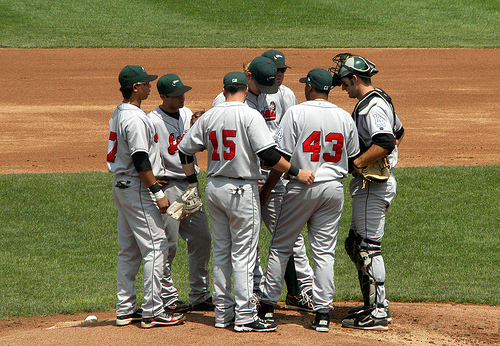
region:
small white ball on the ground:
[80, 306, 114, 328]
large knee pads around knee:
[351, 228, 406, 283]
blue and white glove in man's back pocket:
[92, 173, 147, 204]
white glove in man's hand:
[152, 184, 217, 237]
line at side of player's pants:
[356, 180, 379, 302]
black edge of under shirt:
[246, 140, 290, 175]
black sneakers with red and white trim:
[129, 306, 195, 329]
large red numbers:
[300, 123, 363, 177]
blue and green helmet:
[327, 50, 379, 79]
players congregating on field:
[98, 34, 429, 276]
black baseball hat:
[118, 66, 157, 83]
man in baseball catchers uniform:
[333, 54, 408, 328]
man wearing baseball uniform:
[185, 69, 278, 334]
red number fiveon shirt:
[222, 126, 236, 162]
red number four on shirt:
[305, 129, 322, 164]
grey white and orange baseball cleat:
[141, 311, 187, 326]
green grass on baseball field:
[2, 1, 497, 53]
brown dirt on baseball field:
[1, 47, 498, 169]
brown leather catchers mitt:
[364, 148, 391, 186]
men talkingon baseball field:
[110, 55, 397, 328]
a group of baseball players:
[51, 26, 432, 336]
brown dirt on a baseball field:
[43, 315, 495, 344]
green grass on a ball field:
[405, 170, 492, 276]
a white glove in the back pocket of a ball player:
[225, 181, 247, 198]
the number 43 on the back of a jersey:
[303, 130, 343, 167]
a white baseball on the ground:
[84, 312, 99, 324]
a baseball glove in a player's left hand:
[355, 164, 392, 188]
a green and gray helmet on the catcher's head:
[335, 56, 376, 78]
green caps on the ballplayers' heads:
[107, 40, 335, 105]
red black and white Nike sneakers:
[143, 309, 193, 324]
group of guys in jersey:
[65, 33, 421, 322]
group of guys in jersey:
[211, 112, 434, 326]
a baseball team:
[108, 42, 397, 333]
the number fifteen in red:
[205, 129, 240, 159]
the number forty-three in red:
[301, 129, 344, 165]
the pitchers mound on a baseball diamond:
[86, 291, 385, 343]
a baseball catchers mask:
[323, 51, 385, 88]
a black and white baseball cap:
[153, 71, 194, 98]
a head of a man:
[114, 59, 157, 102]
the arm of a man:
[134, 154, 172, 219]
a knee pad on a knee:
[351, 233, 389, 273]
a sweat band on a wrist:
[146, 184, 171, 199]